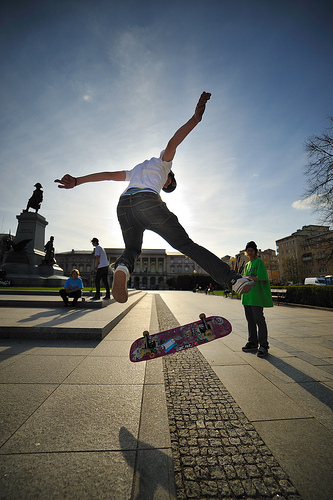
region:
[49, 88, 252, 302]
person in mid-air above skateboard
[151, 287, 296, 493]
bricks in pavement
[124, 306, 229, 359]
skateboard in air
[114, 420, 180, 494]
shadow of skateboard on the ground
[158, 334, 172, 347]
blue and white name tag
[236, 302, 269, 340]
person wearing dark pants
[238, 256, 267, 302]
person wearing green shirt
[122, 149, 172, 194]
person wearing white shirt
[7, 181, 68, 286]
statue on large pedestal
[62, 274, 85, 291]
person wearing blue shirt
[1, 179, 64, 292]
a monument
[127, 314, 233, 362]
skating board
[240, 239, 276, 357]
a boy in a green t-shirt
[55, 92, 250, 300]
a man in the air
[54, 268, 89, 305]
a man sitting down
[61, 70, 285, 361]
a man skating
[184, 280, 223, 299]
a man sitting on a bench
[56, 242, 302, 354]
two man watching a skating man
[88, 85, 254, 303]
two men in a white t-shirt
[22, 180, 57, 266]
two statue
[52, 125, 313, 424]
skateboarder performing jump outside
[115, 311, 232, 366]
bottom of skateboard filled with colorful designs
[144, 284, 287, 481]
stripe composed of rows of square rocks down the plaza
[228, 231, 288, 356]
person in long shirt watching the skateboarder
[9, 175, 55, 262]
statue of historic figure standing on tall foundation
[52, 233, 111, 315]
person sitting on plaza step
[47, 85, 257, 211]
skateboard's arms raised and flung back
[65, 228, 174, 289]
building formed with columns and arches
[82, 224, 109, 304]
person in hat standing on plaza step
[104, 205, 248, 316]
bent and straight legs of skateboarder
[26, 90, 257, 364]
Skateboarder performing a trick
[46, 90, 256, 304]
A person suspended in the air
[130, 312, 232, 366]
The underside of a skate board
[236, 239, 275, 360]
A person in a green shirt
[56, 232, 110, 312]
Two people with skate boards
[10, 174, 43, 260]
A monument with a statue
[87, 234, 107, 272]
A person wearing a white shirt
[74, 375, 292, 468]
A patch of paved pavement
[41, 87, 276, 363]
Four people skate boarding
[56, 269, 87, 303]
A person in a blue shirt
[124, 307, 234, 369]
a rad skateboard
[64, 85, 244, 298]
a cool guy riding a skateboard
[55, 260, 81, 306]
a guy in a blue shirt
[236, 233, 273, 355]
a guy watching someone skateboard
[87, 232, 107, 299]
a person with a black hat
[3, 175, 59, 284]
an old statue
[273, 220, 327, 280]
a bunch of buildings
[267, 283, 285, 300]
a bench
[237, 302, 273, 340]
a pair of black jeans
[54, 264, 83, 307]
a guy sitting down